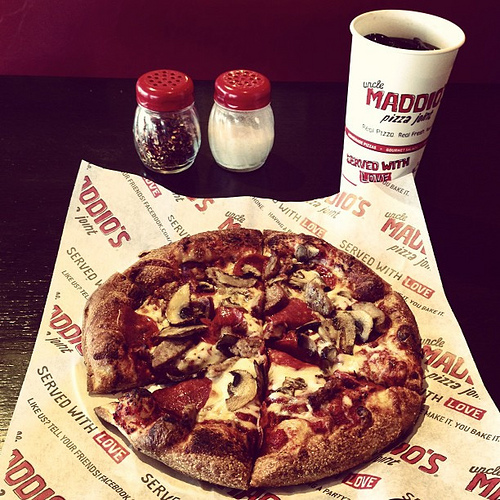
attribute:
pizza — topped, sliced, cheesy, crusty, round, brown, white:
[82, 238, 446, 490]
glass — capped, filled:
[126, 108, 286, 181]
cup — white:
[341, 5, 470, 213]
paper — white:
[32, 156, 498, 492]